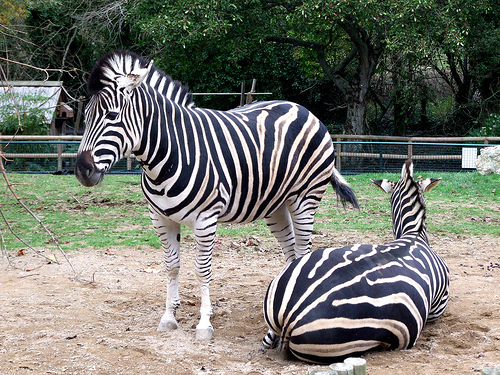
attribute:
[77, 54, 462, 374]
stripes — black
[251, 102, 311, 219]
stripe — black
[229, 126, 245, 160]
stripe — black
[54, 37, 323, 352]
zebra — standing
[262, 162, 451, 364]
zebra — laying, resting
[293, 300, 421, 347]
stripe — black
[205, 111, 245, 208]
stripe — black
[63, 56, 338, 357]
zebra — standing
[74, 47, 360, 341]
zebra — standing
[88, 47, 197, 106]
mane — white, black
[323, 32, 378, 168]
tree trunk — wood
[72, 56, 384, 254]
zebra — standing , looking 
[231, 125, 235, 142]
stripe — black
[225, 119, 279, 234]
stripe — black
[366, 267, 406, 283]
stripe — black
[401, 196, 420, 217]
stripe — black 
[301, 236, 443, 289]
back — laying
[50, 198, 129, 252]
grass — green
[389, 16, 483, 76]
leaves — green 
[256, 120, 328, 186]
stripe — black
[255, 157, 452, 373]
zebra — laying, laying down, sitting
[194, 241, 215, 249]
stripe — black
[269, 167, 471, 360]
zebra — laying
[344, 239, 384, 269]
stripe — black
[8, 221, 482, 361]
ground — dirt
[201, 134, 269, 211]
stripe — black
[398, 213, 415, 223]
stripe — black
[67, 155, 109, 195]
nose — black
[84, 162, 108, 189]
mouth — black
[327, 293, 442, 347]
stripe — black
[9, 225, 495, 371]
ground — dirt